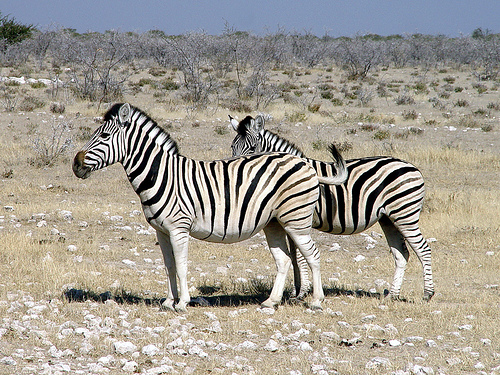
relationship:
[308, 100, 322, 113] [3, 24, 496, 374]
scrub brush growing on ground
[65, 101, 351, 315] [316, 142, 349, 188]
zebra has a long tail with black tip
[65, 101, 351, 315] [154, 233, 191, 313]
zebra has two front legs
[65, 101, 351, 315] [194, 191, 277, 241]
zebra with fat round stomach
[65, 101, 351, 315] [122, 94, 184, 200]
zebra has mane down to its neck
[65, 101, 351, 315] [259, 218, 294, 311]
zebra has white inside back two legs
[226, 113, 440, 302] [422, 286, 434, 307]
zebra has a black hoof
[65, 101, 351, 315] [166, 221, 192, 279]
zebra leg has faded stripes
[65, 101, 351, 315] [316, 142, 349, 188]
zebra ha tail with black tip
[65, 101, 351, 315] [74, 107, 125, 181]
zebra has stripes all over face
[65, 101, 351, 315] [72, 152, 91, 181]
zebra has black nose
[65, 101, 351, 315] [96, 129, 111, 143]
zebra has dark eyes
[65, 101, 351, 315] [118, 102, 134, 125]
zebra has white ears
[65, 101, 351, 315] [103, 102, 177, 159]
zebra has black  white mane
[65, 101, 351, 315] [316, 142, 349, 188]
zebra has a tail with black tip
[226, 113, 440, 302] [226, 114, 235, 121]
zebra has a black tip on ear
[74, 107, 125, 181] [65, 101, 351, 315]
face of th zebra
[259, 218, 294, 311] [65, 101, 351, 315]
back two legs of th zebra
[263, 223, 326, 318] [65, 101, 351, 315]
back two legs of zebra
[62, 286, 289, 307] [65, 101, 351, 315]
shadow of th zebra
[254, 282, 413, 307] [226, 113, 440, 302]
shadow of th zebra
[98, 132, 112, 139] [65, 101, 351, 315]
dark eyes of th zebra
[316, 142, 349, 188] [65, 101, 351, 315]
tail with black tip of th zebra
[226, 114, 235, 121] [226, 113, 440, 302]
ear of th zebra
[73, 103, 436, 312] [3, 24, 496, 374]
two zebras standing on ground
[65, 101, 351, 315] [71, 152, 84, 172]
zebra has a brown black nose